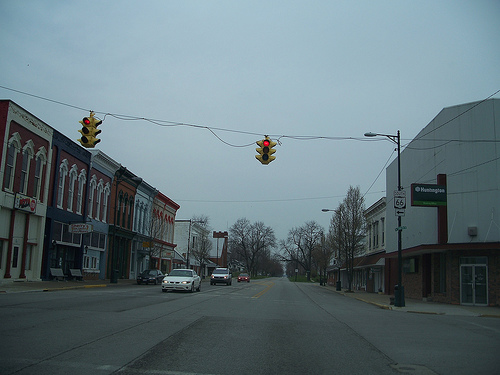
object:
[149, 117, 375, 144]
wire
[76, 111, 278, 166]
lights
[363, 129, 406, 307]
lamp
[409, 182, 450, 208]
signs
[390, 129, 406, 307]
post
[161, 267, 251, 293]
cars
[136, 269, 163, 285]
car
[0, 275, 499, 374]
road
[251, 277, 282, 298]
lines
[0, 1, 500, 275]
skies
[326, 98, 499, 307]
building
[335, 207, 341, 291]
pole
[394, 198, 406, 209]
sign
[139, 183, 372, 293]
tree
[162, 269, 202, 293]
car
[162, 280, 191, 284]
headlight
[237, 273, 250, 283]
car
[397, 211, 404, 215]
arrow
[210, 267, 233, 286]
suv